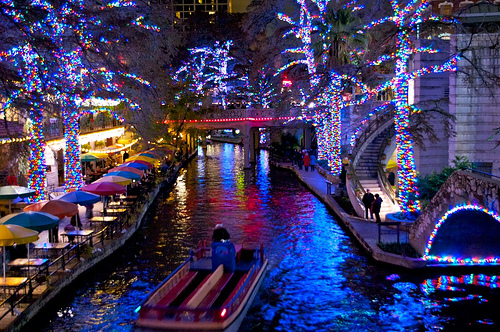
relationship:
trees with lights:
[2, 2, 160, 200] [60, 52, 81, 71]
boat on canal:
[126, 229, 268, 325] [47, 136, 364, 332]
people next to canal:
[354, 185, 388, 220] [47, 136, 364, 332]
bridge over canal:
[155, 99, 305, 170] [47, 136, 364, 332]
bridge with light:
[155, 99, 305, 170] [158, 113, 296, 122]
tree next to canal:
[358, 4, 442, 214] [47, 136, 364, 332]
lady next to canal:
[300, 152, 311, 170] [47, 136, 364, 332]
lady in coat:
[300, 152, 311, 170] [302, 154, 310, 165]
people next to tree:
[354, 185, 388, 220] [358, 4, 442, 214]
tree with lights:
[358, 4, 442, 214] [395, 57, 404, 68]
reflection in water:
[171, 169, 193, 218] [181, 166, 291, 244]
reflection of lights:
[171, 169, 193, 218] [60, 52, 81, 71]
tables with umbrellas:
[2, 240, 69, 298] [2, 197, 68, 255]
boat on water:
[126, 229, 268, 325] [181, 166, 291, 244]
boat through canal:
[126, 229, 268, 325] [47, 136, 364, 332]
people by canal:
[278, 141, 313, 169] [47, 136, 364, 332]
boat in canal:
[126, 229, 268, 325] [47, 136, 364, 332]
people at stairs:
[354, 185, 388, 220] [351, 105, 405, 215]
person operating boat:
[212, 224, 229, 240] [126, 229, 268, 325]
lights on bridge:
[395, 57, 404, 68] [155, 99, 305, 170]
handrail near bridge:
[265, 147, 288, 163] [155, 99, 305, 170]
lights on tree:
[395, 57, 404, 68] [358, 4, 442, 214]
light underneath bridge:
[158, 113, 296, 122] [155, 99, 305, 170]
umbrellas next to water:
[2, 197, 68, 255] [181, 166, 291, 244]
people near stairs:
[354, 185, 388, 220] [351, 105, 405, 215]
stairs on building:
[351, 105, 405, 215] [331, 30, 496, 181]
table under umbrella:
[2, 274, 28, 297] [0, 218, 39, 268]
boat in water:
[126, 229, 268, 325] [181, 166, 291, 244]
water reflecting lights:
[181, 166, 291, 244] [60, 52, 81, 71]